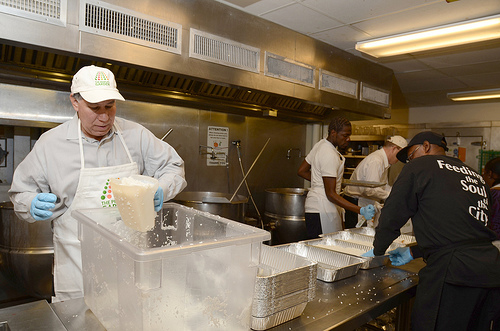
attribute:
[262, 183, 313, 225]
pot — metal, large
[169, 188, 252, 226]
pot — metal, large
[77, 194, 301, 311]
tub — clear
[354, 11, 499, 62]
ceiling light — white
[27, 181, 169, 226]
gloves — blue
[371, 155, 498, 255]
shirt — black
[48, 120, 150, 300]
apron — white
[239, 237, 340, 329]
pans — foil, empty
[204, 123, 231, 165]
sign — warning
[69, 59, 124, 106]
cap — white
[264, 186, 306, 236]
containers — cooking, silver, large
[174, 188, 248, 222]
containers — large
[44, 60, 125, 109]
hat — white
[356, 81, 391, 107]
vent — silver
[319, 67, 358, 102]
vent — silver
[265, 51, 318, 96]
vent — silver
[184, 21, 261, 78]
vent — silver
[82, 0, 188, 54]
vent — silver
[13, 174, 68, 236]
gloves — rubber, blue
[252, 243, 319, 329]
pans — aluminum, stacked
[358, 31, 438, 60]
light — flourescent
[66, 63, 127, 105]
baseball cap — white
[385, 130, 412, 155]
baseball cap — white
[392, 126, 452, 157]
baseball cap — white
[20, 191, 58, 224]
glove — vinyl, blue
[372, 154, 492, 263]
shirt — black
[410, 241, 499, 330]
pants — black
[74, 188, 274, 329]
container — large, plastic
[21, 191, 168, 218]
gloves — blue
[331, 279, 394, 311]
crumbs — spilled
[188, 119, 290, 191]
wall — stainless steel